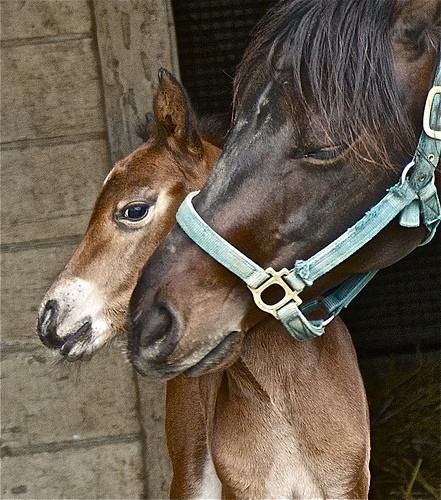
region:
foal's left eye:
[109, 193, 156, 230]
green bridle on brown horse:
[176, 46, 439, 341]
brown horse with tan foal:
[34, 17, 437, 498]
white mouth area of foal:
[36, 273, 114, 361]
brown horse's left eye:
[291, 129, 362, 168]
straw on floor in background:
[388, 342, 436, 497]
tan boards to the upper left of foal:
[9, 32, 80, 236]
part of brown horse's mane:
[281, 19, 417, 159]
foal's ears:
[130, 64, 208, 157]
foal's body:
[169, 369, 372, 498]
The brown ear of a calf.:
[143, 69, 204, 157]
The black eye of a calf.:
[103, 193, 166, 229]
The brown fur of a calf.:
[246, 366, 340, 463]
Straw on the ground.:
[378, 378, 438, 472]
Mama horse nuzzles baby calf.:
[22, 86, 415, 385]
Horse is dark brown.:
[243, 67, 377, 199]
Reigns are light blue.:
[178, 216, 325, 319]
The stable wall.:
[2, 364, 125, 496]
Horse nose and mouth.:
[124, 302, 248, 383]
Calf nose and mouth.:
[32, 292, 108, 374]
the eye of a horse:
[113, 192, 158, 227]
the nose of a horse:
[28, 288, 70, 348]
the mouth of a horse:
[173, 321, 247, 378]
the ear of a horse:
[150, 62, 206, 155]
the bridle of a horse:
[170, 51, 440, 347]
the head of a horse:
[17, 71, 237, 379]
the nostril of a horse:
[136, 302, 178, 356]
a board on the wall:
[0, 31, 110, 148]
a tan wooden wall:
[0, 0, 189, 498]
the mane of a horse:
[131, 103, 243, 156]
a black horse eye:
[102, 191, 161, 230]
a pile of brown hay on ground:
[378, 361, 435, 498]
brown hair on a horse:
[288, 20, 390, 115]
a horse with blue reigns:
[180, 70, 439, 329]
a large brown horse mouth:
[127, 301, 244, 382]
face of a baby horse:
[30, 68, 220, 377]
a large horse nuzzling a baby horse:
[40, 86, 411, 392]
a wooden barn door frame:
[97, 0, 178, 70]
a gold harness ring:
[246, 259, 301, 324]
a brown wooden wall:
[0, 35, 93, 162]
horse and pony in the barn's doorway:
[33, 0, 439, 498]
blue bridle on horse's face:
[178, 62, 439, 341]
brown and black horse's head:
[121, 0, 439, 383]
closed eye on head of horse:
[301, 131, 360, 165]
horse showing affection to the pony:
[36, 4, 439, 498]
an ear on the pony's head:
[150, 64, 206, 155]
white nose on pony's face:
[30, 279, 108, 362]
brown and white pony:
[34, 66, 369, 498]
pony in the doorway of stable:
[35, 69, 376, 498]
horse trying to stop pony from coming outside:
[34, 2, 440, 497]